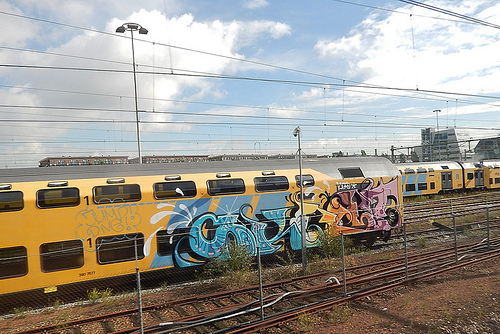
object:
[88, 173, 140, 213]
window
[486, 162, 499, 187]
passenger car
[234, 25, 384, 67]
blue sky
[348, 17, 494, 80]
white cloud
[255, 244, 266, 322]
post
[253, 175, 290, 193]
long window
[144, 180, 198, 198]
window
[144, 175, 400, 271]
graffiti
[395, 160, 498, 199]
train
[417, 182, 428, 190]
window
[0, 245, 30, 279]
lower window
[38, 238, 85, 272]
lower window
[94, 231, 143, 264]
lower window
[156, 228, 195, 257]
lower window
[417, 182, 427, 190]
lower window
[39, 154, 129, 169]
apartment building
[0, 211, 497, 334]
fence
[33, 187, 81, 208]
window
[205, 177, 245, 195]
window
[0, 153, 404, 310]
train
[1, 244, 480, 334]
rail yard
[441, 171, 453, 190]
door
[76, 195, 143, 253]
graffiti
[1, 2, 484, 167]
sky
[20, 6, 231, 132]
cloud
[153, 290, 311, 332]
line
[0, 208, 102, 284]
paint